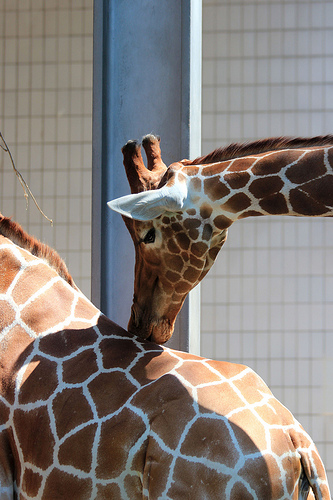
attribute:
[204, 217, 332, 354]
wall — white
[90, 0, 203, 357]
beam — steel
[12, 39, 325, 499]
giraffes — spotted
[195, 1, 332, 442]
building — white, tile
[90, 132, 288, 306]
giraffe — brown, white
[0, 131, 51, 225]
tree branch — small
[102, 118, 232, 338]
head — giraffe head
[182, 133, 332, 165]
mane — brown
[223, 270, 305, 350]
tile — white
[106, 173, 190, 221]
ear — white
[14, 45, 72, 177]
back wall — white tile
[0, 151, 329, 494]
giraffe coats — spotted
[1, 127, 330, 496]
giraffes. — captive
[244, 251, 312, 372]
tile — white